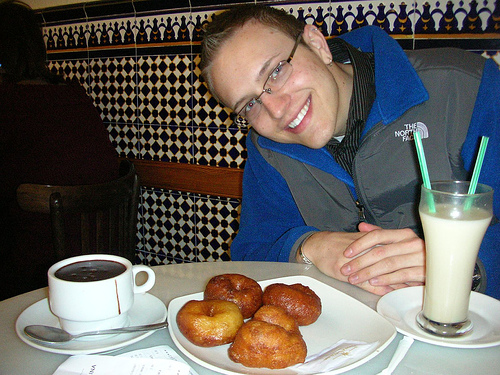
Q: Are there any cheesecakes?
A: No, there are no cheesecakes.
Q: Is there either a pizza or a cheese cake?
A: No, there are no cheesecakes or pizzas.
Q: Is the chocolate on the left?
A: Yes, the chocolate is on the left of the image.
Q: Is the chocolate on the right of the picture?
A: No, the chocolate is on the left of the image.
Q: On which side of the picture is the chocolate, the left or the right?
A: The chocolate is on the left of the image.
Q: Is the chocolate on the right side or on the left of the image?
A: The chocolate is on the left of the image.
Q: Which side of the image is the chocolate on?
A: The chocolate is on the left of the image.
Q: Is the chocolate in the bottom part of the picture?
A: Yes, the chocolate is in the bottom of the image.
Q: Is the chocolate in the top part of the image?
A: No, the chocolate is in the bottom of the image.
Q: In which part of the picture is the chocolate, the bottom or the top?
A: The chocolate is in the bottom of the image.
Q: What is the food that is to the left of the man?
A: The food is chocolate.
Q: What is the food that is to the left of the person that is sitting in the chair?
A: The food is chocolate.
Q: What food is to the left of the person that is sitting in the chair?
A: The food is chocolate.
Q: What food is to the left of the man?
A: The food is chocolate.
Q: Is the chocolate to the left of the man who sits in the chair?
A: Yes, the chocolate is to the left of the man.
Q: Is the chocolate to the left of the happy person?
A: Yes, the chocolate is to the left of the man.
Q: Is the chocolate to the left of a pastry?
A: No, the chocolate is to the left of the man.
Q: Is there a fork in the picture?
A: No, there are no forks.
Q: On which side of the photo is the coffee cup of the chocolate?
A: The coffee cup is on the left of the image.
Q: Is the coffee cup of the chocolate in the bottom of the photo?
A: Yes, the coffee cup is in the bottom of the image.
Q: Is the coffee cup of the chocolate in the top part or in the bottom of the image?
A: The coffee cup is in the bottom of the image.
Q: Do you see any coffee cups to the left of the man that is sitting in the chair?
A: Yes, there is a coffee cup to the left of the man.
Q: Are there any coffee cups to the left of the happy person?
A: Yes, there is a coffee cup to the left of the man.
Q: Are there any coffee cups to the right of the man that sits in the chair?
A: No, the coffee cup is to the left of the man.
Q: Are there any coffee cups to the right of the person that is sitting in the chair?
A: No, the coffee cup is to the left of the man.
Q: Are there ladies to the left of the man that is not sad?
A: No, there is a coffee cup to the left of the man.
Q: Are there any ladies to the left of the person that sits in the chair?
A: No, there is a coffee cup to the left of the man.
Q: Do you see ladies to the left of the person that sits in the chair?
A: No, there is a coffee cup to the left of the man.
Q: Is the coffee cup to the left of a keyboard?
A: No, the coffee cup is to the left of the man.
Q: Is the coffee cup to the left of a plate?
A: Yes, the coffee cup is to the left of a plate.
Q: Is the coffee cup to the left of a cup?
A: No, the coffee cup is to the left of a plate.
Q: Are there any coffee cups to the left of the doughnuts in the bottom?
A: Yes, there is a coffee cup to the left of the donuts.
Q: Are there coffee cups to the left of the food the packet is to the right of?
A: Yes, there is a coffee cup to the left of the donuts.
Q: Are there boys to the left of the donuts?
A: No, there is a coffee cup to the left of the donuts.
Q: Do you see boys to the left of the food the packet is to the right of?
A: No, there is a coffee cup to the left of the donuts.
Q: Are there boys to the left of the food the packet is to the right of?
A: No, there is a coffee cup to the left of the donuts.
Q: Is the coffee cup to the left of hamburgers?
A: No, the coffee cup is to the left of the doughnuts.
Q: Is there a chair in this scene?
A: Yes, there is a chair.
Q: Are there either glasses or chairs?
A: Yes, there is a chair.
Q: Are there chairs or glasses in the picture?
A: Yes, there is a chair.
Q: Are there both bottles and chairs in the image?
A: No, there is a chair but no bottles.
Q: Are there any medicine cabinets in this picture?
A: No, there are no medicine cabinets.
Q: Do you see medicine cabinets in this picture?
A: No, there are no medicine cabinets.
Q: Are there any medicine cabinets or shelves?
A: No, there are no medicine cabinets or shelves.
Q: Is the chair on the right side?
A: No, the chair is on the left of the image.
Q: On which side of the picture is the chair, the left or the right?
A: The chair is on the left of the image.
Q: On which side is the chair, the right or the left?
A: The chair is on the left of the image.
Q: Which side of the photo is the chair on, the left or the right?
A: The chair is on the left of the image.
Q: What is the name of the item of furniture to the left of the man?
A: The piece of furniture is a chair.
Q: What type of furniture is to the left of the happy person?
A: The piece of furniture is a chair.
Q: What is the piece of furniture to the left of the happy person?
A: The piece of furniture is a chair.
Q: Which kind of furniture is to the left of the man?
A: The piece of furniture is a chair.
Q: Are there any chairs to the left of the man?
A: Yes, there is a chair to the left of the man.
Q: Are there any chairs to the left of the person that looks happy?
A: Yes, there is a chair to the left of the man.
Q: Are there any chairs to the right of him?
A: No, the chair is to the left of the man.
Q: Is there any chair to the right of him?
A: No, the chair is to the left of the man.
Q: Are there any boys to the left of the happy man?
A: No, there is a chair to the left of the man.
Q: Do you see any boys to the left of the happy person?
A: No, there is a chair to the left of the man.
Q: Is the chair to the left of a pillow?
A: No, the chair is to the left of the man.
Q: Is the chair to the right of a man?
A: No, the chair is to the left of a man.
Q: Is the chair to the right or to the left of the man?
A: The chair is to the left of the man.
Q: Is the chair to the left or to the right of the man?
A: The chair is to the left of the man.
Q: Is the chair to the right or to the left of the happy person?
A: The chair is to the left of the man.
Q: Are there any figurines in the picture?
A: No, there are no figurines.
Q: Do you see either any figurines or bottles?
A: No, there are no figurines or bottles.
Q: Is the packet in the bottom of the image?
A: Yes, the packet is in the bottom of the image.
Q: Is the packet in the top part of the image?
A: No, the packet is in the bottom of the image.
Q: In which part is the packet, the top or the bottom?
A: The packet is in the bottom of the image.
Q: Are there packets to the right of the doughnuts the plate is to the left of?
A: Yes, there is a packet to the right of the donuts.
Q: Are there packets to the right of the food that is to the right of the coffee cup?
A: Yes, there is a packet to the right of the donuts.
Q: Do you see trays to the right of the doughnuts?
A: No, there is a packet to the right of the doughnuts.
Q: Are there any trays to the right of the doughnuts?
A: No, there is a packet to the right of the doughnuts.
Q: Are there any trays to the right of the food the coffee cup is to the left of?
A: No, there is a packet to the right of the doughnuts.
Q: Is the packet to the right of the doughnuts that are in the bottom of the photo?
A: Yes, the packet is to the right of the doughnuts.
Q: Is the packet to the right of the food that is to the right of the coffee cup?
A: Yes, the packet is to the right of the doughnuts.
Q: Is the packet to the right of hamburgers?
A: No, the packet is to the right of the doughnuts.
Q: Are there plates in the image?
A: Yes, there is a plate.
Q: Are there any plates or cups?
A: Yes, there is a plate.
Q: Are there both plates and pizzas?
A: No, there is a plate but no pizzas.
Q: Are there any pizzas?
A: No, there are no pizzas.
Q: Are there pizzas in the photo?
A: No, there are no pizzas.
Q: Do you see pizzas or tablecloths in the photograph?
A: No, there are no pizzas or tablecloths.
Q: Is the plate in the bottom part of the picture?
A: Yes, the plate is in the bottom of the image.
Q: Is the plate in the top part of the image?
A: No, the plate is in the bottom of the image.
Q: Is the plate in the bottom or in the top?
A: The plate is in the bottom of the image.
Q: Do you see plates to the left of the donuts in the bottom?
A: Yes, there is a plate to the left of the donuts.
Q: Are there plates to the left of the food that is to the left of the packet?
A: Yes, there is a plate to the left of the donuts.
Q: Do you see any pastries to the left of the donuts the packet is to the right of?
A: No, there is a plate to the left of the donuts.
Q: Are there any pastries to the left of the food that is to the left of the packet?
A: No, there is a plate to the left of the donuts.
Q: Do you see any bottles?
A: No, there are no bottles.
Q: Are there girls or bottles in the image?
A: No, there are no bottles or girls.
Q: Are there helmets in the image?
A: No, there are no helmets.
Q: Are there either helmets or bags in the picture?
A: No, there are no helmets or bags.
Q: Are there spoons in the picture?
A: Yes, there is a spoon.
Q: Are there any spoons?
A: Yes, there is a spoon.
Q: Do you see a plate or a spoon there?
A: Yes, there is a spoon.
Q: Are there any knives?
A: No, there are no knives.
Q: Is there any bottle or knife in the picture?
A: No, there are no knives or bottles.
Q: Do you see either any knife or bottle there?
A: No, there are no knives or bottles.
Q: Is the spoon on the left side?
A: Yes, the spoon is on the left of the image.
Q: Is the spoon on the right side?
A: No, the spoon is on the left of the image.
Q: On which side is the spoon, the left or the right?
A: The spoon is on the left of the image.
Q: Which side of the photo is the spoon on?
A: The spoon is on the left of the image.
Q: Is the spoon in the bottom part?
A: Yes, the spoon is in the bottom of the image.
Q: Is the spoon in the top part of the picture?
A: No, the spoon is in the bottom of the image.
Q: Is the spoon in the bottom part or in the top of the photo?
A: The spoon is in the bottom of the image.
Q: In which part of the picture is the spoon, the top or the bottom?
A: The spoon is in the bottom of the image.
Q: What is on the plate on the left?
A: The spoon is on the plate.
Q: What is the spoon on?
A: The spoon is on the plate.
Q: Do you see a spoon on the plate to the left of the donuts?
A: Yes, there is a spoon on the plate.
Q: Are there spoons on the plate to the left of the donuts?
A: Yes, there is a spoon on the plate.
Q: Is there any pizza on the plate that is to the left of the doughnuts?
A: No, there is a spoon on the plate.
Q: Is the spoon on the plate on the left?
A: Yes, the spoon is on the plate.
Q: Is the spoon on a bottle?
A: No, the spoon is on the plate.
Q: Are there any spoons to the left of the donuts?
A: Yes, there is a spoon to the left of the donuts.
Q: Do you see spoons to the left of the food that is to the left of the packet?
A: Yes, there is a spoon to the left of the donuts.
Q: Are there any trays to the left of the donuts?
A: No, there is a spoon to the left of the donuts.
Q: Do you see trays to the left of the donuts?
A: No, there is a spoon to the left of the donuts.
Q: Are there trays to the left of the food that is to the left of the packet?
A: No, there is a spoon to the left of the donuts.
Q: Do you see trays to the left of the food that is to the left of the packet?
A: No, there is a spoon to the left of the donuts.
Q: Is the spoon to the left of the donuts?
A: Yes, the spoon is to the left of the donuts.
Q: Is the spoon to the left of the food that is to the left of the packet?
A: Yes, the spoon is to the left of the donuts.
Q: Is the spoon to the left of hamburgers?
A: No, the spoon is to the left of the donuts.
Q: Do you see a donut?
A: Yes, there are donuts.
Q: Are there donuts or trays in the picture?
A: Yes, there are donuts.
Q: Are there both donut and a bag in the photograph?
A: No, there are donuts but no bags.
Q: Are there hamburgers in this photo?
A: No, there are no hamburgers.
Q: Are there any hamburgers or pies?
A: No, there are no hamburgers or pies.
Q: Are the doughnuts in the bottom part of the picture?
A: Yes, the doughnuts are in the bottom of the image.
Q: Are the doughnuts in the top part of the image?
A: No, the doughnuts are in the bottom of the image.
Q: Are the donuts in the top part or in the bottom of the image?
A: The donuts are in the bottom of the image.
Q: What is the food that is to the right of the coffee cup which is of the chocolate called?
A: The food is donuts.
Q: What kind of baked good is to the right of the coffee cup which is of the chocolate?
A: The food is donuts.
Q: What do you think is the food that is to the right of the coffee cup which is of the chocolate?
A: The food is donuts.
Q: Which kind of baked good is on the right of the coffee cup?
A: The food is donuts.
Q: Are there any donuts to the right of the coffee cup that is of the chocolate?
A: Yes, there are donuts to the right of the coffee cup.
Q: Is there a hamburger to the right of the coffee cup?
A: No, there are donuts to the right of the coffee cup.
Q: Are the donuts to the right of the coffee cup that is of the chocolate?
A: Yes, the donuts are to the right of the coffee cup.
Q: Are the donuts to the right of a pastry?
A: No, the donuts are to the right of the coffee cup.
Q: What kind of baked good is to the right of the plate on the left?
A: The food is donuts.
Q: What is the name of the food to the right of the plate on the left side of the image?
A: The food is donuts.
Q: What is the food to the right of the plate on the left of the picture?
A: The food is donuts.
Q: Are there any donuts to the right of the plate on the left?
A: Yes, there are donuts to the right of the plate.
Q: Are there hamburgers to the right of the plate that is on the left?
A: No, there are donuts to the right of the plate.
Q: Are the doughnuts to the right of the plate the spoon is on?
A: Yes, the doughnuts are to the right of the plate.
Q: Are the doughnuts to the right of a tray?
A: No, the doughnuts are to the right of the plate.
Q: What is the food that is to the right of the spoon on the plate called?
A: The food is donuts.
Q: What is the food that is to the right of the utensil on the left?
A: The food is donuts.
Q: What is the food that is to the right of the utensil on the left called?
A: The food is donuts.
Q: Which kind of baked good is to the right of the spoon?
A: The food is donuts.